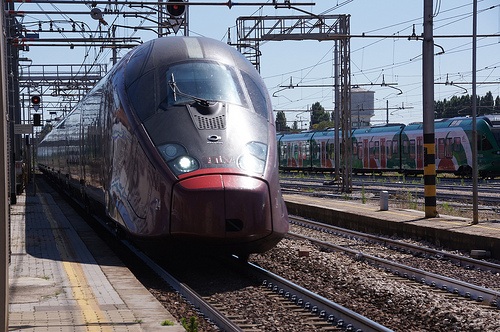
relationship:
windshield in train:
[127, 61, 268, 124] [31, 42, 358, 298]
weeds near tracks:
[179, 315, 203, 330] [40, 172, 395, 330]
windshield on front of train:
[119, 56, 271, 125] [26, 33, 291, 260]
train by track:
[26, 33, 291, 260] [158, 254, 394, 329]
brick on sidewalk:
[41, 295, 48, 307] [3, 180, 187, 329]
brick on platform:
[7, 173, 187, 332] [9, 181, 185, 332]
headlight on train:
[168, 155, 200, 175] [26, 33, 291, 260]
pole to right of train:
[411, 0, 448, 210] [26, 33, 291, 260]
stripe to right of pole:
[424, 132, 434, 144] [422, 5, 435, 215]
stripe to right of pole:
[422, 154, 433, 164] [422, 5, 435, 215]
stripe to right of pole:
[423, 175, 438, 188] [422, 5, 435, 215]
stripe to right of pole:
[422, 193, 439, 207] [422, 5, 435, 215]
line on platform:
[35, 189, 112, 331] [9, 169, 185, 329]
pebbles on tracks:
[140, 211, 499, 326] [120, 200, 498, 326]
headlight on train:
[173, 155, 199, 173] [281, 106, 499, 183]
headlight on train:
[236, 155, 256, 170] [281, 106, 499, 183]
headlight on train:
[161, 142, 176, 157] [281, 106, 499, 183]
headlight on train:
[248, 143, 261, 155] [281, 106, 499, 183]